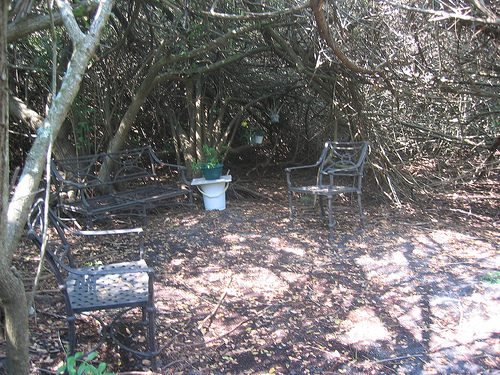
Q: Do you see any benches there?
A: Yes, there is a bench.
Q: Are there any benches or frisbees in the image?
A: Yes, there is a bench.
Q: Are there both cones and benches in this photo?
A: No, there is a bench but no cones.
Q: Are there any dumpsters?
A: No, there are no dumpsters.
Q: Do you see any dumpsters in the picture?
A: No, there are no dumpsters.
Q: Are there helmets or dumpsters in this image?
A: No, there are no dumpsters or helmets.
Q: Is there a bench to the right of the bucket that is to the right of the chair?
A: Yes, there is a bench to the right of the bucket.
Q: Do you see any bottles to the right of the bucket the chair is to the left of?
A: No, there is a bench to the right of the bucket.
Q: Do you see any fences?
A: No, there are no fences.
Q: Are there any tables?
A: Yes, there is a table.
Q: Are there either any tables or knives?
A: Yes, there is a table.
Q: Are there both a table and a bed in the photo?
A: No, there is a table but no beds.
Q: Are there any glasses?
A: No, there are no glasses.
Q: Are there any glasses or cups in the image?
A: No, there are no glasses or cups.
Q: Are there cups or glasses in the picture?
A: No, there are no glasses or cups.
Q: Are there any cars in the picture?
A: No, there are no cars.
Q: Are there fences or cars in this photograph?
A: No, there are no cars or fences.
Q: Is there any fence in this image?
A: No, there are no fences.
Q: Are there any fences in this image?
A: No, there are no fences.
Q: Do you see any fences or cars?
A: No, there are no fences or cars.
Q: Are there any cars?
A: No, there are no cars.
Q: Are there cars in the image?
A: No, there are no cars.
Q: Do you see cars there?
A: No, there are no cars.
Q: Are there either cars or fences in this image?
A: No, there are no cars or fences.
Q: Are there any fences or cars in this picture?
A: No, there are no cars or fences.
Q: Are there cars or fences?
A: No, there are no cars or fences.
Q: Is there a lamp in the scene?
A: No, there are no lamps.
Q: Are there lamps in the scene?
A: No, there are no lamps.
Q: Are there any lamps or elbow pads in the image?
A: No, there are no lamps or elbow pads.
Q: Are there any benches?
A: Yes, there is a bench.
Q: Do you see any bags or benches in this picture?
A: Yes, there is a bench.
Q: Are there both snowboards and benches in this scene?
A: No, there is a bench but no snowboards.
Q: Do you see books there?
A: No, there are no books.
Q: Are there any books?
A: No, there are no books.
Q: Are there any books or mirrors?
A: No, there are no books or mirrors.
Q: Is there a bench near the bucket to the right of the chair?
A: Yes, there is a bench near the bucket.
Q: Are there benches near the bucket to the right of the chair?
A: Yes, there is a bench near the bucket.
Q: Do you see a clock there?
A: No, there are no clocks.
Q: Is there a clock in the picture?
A: No, there are no clocks.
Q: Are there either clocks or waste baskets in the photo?
A: No, there are no clocks or waste baskets.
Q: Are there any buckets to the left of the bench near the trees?
A: Yes, there is a bucket to the left of the bench.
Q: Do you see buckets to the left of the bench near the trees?
A: Yes, there is a bucket to the left of the bench.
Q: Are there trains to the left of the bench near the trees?
A: No, there is a bucket to the left of the bench.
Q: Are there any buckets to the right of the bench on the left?
A: Yes, there is a bucket to the right of the bench.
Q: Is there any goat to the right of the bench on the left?
A: No, there is a bucket to the right of the bench.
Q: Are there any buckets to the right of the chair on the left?
A: Yes, there is a bucket to the right of the chair.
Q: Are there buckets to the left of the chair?
A: No, the bucket is to the right of the chair.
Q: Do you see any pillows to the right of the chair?
A: No, there is a bucket to the right of the chair.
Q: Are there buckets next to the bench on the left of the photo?
A: Yes, there is a bucket next to the bench.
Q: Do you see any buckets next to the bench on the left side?
A: Yes, there is a bucket next to the bench.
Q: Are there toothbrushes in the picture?
A: No, there are no toothbrushes.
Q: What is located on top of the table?
A: The plant is on top of the table.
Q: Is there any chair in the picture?
A: Yes, there is a chair.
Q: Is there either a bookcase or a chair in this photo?
A: Yes, there is a chair.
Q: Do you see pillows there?
A: No, there are no pillows.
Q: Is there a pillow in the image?
A: No, there are no pillows.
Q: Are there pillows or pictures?
A: No, there are no pillows or pictures.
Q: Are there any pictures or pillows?
A: No, there are no pillows or pictures.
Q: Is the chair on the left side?
A: Yes, the chair is on the left of the image.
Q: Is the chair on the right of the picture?
A: No, the chair is on the left of the image.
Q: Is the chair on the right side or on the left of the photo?
A: The chair is on the left of the image.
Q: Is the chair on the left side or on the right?
A: The chair is on the left of the image.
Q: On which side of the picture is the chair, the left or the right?
A: The chair is on the left of the image.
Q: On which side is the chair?
A: The chair is on the left of the image.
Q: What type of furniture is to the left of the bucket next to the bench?
A: The piece of furniture is a chair.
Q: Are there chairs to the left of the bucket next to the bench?
A: Yes, there is a chair to the left of the bucket.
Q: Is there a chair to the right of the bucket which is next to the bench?
A: No, the chair is to the left of the bucket.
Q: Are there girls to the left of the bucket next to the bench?
A: No, there is a chair to the left of the bucket.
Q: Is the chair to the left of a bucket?
A: Yes, the chair is to the left of a bucket.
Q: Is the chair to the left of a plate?
A: No, the chair is to the left of a bucket.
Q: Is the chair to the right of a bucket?
A: No, the chair is to the left of a bucket.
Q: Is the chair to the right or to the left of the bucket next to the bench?
A: The chair is to the left of the bucket.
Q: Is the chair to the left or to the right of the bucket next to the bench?
A: The chair is to the left of the bucket.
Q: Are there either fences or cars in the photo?
A: No, there are no cars or fences.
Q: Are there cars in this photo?
A: No, there are no cars.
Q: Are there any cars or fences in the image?
A: No, there are no cars or fences.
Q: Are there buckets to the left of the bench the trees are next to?
A: Yes, there is a bucket to the left of the bench.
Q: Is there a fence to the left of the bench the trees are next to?
A: No, there is a bucket to the left of the bench.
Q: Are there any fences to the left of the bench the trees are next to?
A: No, there is a bucket to the left of the bench.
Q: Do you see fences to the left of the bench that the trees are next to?
A: No, there is a bucket to the left of the bench.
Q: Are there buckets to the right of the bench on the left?
A: Yes, there is a bucket to the right of the bench.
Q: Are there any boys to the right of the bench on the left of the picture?
A: No, there is a bucket to the right of the bench.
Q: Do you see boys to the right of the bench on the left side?
A: No, there is a bucket to the right of the bench.